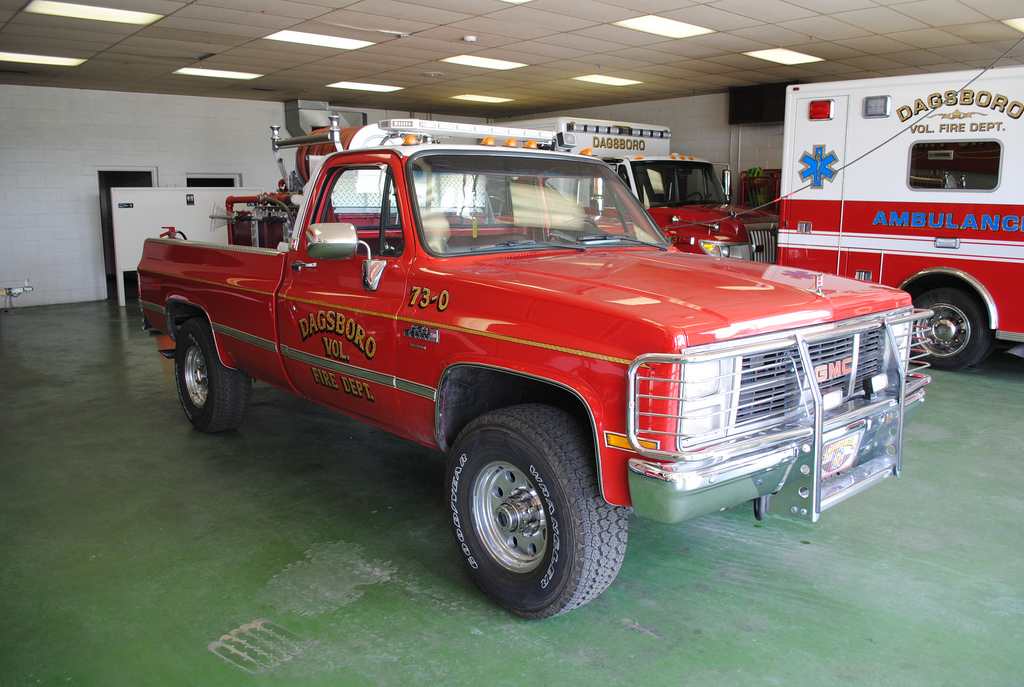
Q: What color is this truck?
A: Red.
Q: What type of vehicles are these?
A: Emergency.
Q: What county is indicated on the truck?
A: Dashboard.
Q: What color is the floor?
A: Green.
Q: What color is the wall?
A: White.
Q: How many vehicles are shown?
A: Three.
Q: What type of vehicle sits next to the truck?
A: An ambulance.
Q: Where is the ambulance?
A: In the garage.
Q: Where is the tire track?
A: On the floor next to the truck.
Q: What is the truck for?
A: The volunteer fire department.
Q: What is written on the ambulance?
A: That it is for the volunteer fire department.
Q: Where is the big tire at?
A: On the truck.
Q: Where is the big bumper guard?
A: On the truck.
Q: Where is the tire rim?
A: On the tire.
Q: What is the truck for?
A: The the firefighters.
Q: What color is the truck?
A: Red.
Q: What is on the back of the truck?
A: Some hoses.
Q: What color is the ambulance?
A: Red and white.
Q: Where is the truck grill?
A: Front.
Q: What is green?
A: Garage floor.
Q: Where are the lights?
A: Ceiling.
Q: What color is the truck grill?
A: Silver.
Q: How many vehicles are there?
A: 3.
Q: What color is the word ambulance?
A: Blue.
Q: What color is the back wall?
A: White.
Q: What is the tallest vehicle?
A: The ambulance.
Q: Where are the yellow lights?
A: Truck roof.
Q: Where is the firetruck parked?
A: Garage.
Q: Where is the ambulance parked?
A: Garage.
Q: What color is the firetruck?
A: Red.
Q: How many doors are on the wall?
A: 2.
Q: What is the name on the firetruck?
A: Dagsboro.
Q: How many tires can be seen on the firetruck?
A: 2.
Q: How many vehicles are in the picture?
A: 3.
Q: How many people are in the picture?
A: 0.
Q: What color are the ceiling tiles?
A: White.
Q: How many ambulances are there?
A: Two.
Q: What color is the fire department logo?
A: Yellow.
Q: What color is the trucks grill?
A: Silver.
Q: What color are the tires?
A: Black.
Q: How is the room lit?
A: From lights on the ceiling.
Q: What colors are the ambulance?
A: Red and white.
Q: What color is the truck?
A: Red.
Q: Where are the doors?
A: Along the wall.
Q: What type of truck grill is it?
A: Heavy duty.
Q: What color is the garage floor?
A: Green.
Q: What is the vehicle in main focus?
A: A truck.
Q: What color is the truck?
A: Red.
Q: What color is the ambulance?
A: Red and white and blue.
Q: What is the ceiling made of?
A: Lights and tiles.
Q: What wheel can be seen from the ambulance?
A: Rear right wheel.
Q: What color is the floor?
A: Green and grey.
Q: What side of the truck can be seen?
A: The passenger side.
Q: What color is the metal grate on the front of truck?
A: Grey stainless steel.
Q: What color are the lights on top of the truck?
A: Orange.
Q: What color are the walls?
A: White.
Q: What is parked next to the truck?
A: An ambulance.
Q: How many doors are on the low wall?
A: Two.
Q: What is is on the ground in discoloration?
A: Brown.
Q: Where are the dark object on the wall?
A: Black.